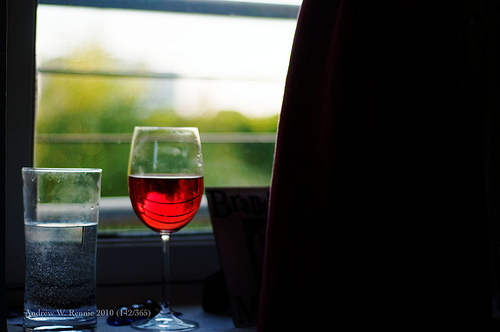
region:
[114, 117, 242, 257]
red wine in a glass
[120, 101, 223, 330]
a clear wine glass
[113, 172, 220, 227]
wine in the wine glass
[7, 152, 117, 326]
a glass of clear water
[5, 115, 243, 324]
two glasses on a table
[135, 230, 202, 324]
stem of the wine glass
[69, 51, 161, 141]
green trees outside of the window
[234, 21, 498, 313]
the back of a chair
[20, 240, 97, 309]
bubbles in the glass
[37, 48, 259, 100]
metal bar in the window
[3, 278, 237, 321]
a side table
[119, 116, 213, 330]
the glass is half full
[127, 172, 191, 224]
the wine is red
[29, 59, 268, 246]
the window is closed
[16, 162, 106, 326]
the glass has water in it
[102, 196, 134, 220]
the bar is silver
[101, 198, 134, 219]
the bar is metal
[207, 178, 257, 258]
the laptop is open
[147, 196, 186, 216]
the reflection is in the glass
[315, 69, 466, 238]
the chair is dark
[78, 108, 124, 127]
the bushes are green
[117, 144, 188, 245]
red wine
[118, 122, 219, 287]
red wine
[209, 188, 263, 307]
the edge of a picture frame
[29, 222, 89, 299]
water in a glass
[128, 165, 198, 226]
red wine in a wine glass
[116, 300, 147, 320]
blue bead on a counter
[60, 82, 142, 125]
green trees outside a window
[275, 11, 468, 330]
a red blanket draped nearby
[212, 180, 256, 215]
black letters on white frame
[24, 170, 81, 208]
a clear drinking glass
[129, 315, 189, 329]
the rounded glass base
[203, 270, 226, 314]
a black cardboard support